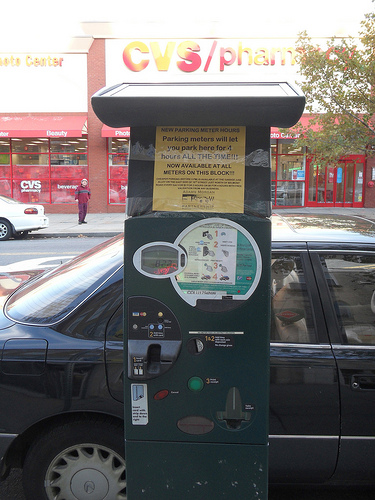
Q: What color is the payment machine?
A: Green.